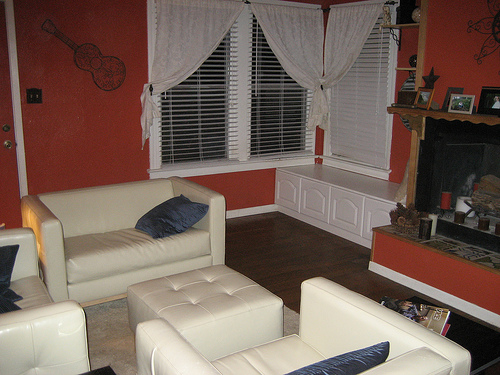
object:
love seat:
[20, 177, 229, 306]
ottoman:
[122, 262, 286, 364]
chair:
[0, 226, 94, 375]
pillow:
[0, 243, 24, 306]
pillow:
[137, 188, 209, 237]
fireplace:
[413, 116, 498, 249]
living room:
[0, 2, 498, 375]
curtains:
[140, 0, 245, 150]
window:
[144, 0, 229, 169]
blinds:
[147, 0, 240, 170]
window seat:
[268, 157, 412, 251]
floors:
[224, 208, 499, 375]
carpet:
[84, 296, 302, 375]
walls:
[0, 0, 322, 231]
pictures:
[474, 86, 499, 110]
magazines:
[377, 296, 451, 335]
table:
[385, 290, 498, 375]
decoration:
[42, 16, 127, 92]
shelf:
[384, 101, 498, 139]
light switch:
[25, 88, 45, 105]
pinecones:
[396, 215, 406, 226]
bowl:
[418, 217, 431, 241]